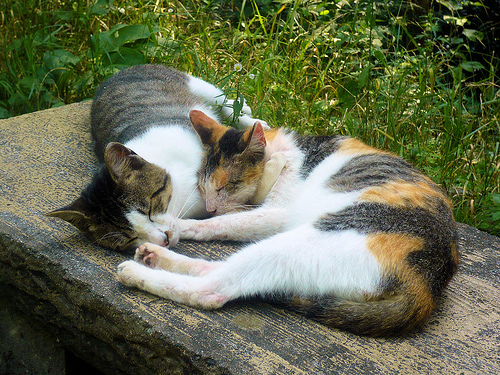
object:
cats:
[114, 108, 460, 335]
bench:
[0, 89, 500, 375]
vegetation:
[82, 14, 402, 59]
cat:
[42, 59, 271, 249]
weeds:
[262, 5, 433, 87]